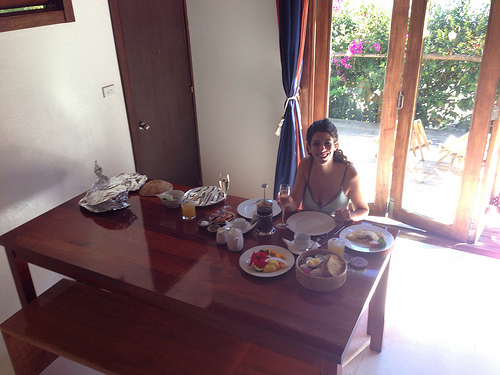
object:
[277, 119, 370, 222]
woman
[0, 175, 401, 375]
table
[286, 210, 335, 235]
plate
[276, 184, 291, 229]
glass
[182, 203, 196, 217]
orange juice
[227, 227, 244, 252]
tea pot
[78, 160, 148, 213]
foil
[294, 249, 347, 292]
basket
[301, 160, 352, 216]
tank top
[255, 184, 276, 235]
coffee press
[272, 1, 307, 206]
curtain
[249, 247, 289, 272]
food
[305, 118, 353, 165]
hair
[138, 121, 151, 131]
handle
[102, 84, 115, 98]
switch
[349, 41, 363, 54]
flower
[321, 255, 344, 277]
bread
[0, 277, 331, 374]
bench